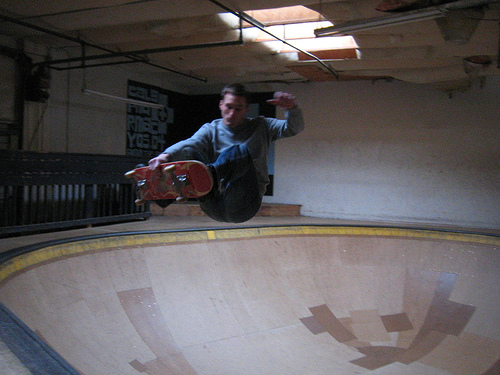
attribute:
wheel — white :
[159, 161, 177, 176]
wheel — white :
[122, 166, 137, 183]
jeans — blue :
[186, 146, 286, 210]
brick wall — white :
[275, 76, 498, 231]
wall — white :
[270, 77, 494, 239]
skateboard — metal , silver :
[117, 151, 223, 212]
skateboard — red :
[93, 138, 243, 218]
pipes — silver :
[83, 3, 350, 96]